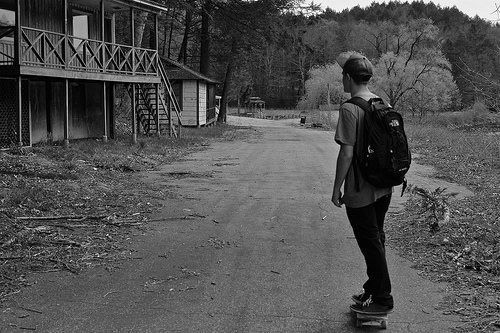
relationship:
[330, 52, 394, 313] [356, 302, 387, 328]
guy riding on his skateboard skateboard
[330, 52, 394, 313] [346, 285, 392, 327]
guy riding a skateboard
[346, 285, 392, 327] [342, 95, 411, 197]
skateboard with a pack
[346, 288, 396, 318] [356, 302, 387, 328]
black shoes on skateboard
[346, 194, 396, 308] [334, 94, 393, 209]
pants and shirt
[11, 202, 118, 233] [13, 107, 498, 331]
limb laying on side of a ground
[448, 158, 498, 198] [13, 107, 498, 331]
leaves are on ground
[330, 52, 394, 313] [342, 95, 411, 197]
guy with a pack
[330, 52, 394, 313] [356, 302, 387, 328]
guy riding a skateboard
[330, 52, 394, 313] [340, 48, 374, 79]
guy wearing cap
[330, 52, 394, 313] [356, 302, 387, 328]
guy on skateboard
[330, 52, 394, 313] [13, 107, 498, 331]
guy on ground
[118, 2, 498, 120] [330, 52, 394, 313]
trees behind guy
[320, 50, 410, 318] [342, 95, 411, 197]
guy wearing pack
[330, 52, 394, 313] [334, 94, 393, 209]
guy wearing shirt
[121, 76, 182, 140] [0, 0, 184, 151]
stairs are on building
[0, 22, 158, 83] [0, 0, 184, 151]
porch on building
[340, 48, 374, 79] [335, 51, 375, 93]
cap on head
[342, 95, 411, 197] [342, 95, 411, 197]
pack on pack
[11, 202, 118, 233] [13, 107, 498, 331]
limb on ground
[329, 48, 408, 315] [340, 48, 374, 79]
man wearing cap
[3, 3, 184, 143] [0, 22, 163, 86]
building with porch